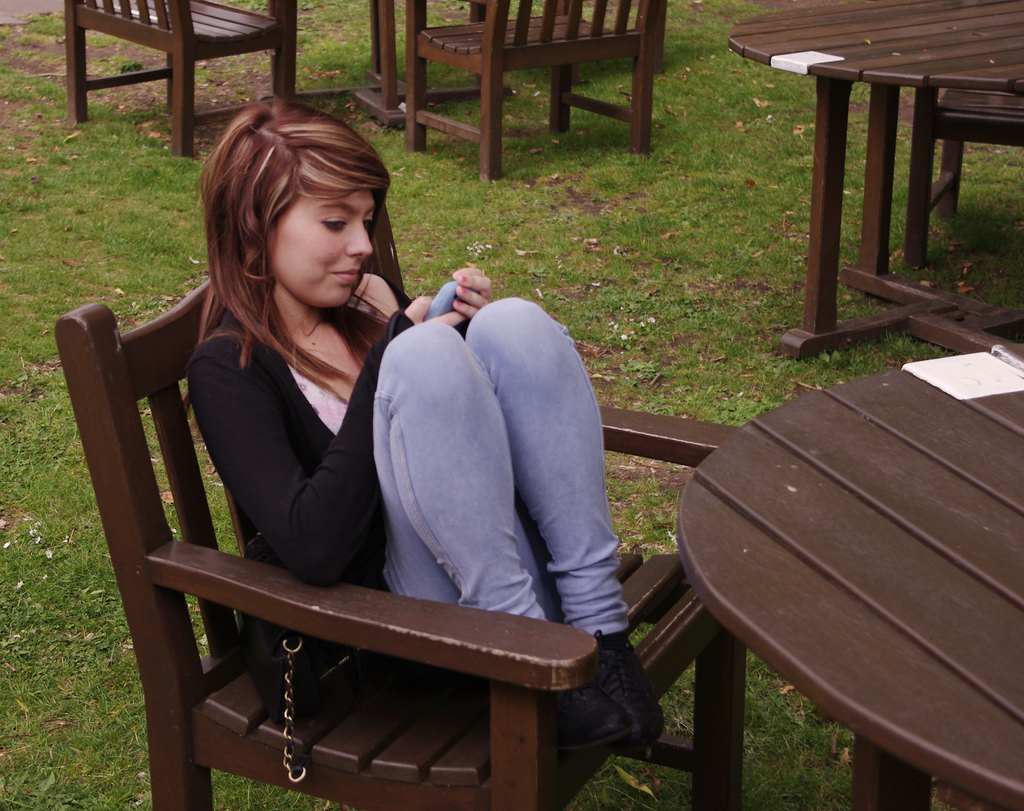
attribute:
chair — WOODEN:
[124, 385, 179, 787]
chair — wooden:
[64, 1, 307, 157]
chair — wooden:
[399, 7, 678, 183]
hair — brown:
[177, 85, 456, 408]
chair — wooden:
[49, 236, 752, 807]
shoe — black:
[512, 625, 670, 751]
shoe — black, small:
[522, 638, 643, 751]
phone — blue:
[408, 270, 482, 348]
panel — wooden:
[134, 383, 245, 669]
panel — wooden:
[146, 366, 248, 660]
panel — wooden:
[795, 61, 841, 334]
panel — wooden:
[572, 398, 774, 476]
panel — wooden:
[615, 536, 685, 627]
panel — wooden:
[622, 543, 752, 704]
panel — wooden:
[432, 539, 690, 797]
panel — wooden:
[371, 541, 646, 805]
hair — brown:
[175, 83, 426, 423]